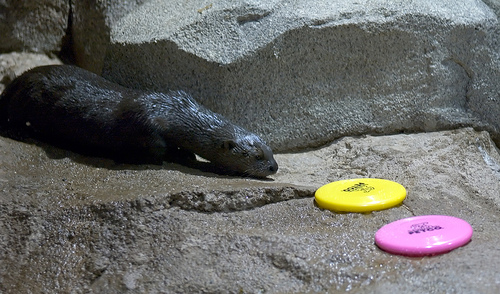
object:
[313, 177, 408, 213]
frisbee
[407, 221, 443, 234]
branding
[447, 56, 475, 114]
crack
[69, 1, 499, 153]
boulder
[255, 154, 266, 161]
eye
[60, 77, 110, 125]
fur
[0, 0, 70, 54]
boulder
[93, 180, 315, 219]
crack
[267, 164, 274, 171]
nostril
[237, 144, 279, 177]
face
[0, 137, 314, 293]
water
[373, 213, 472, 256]
frisbee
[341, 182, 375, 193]
branding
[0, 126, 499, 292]
boulder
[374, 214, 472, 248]
top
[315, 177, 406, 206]
top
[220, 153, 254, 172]
side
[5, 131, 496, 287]
ground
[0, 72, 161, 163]
side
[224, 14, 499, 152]
side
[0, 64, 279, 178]
animal